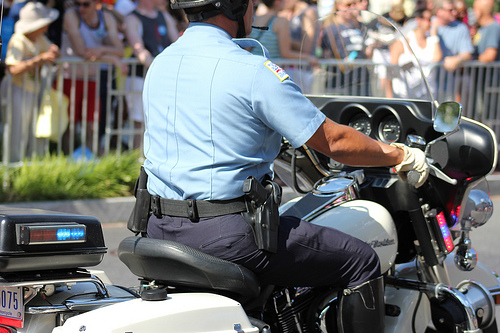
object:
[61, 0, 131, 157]
person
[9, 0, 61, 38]
hat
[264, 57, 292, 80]
patch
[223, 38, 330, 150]
sleeve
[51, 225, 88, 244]
blue light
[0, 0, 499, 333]
bike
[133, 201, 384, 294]
blue pants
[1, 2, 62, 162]
people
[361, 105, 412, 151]
odometer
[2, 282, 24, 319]
license plate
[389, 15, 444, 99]
person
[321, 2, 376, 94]
person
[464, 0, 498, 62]
person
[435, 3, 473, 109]
person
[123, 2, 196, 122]
person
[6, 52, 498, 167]
gate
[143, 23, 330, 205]
shirt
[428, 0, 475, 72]
people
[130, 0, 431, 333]
an officer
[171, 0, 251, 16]
cap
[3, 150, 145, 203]
grass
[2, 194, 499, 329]
street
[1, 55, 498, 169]
fence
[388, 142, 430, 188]
glove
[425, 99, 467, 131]
mirror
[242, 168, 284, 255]
gun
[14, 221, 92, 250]
light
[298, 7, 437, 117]
visor